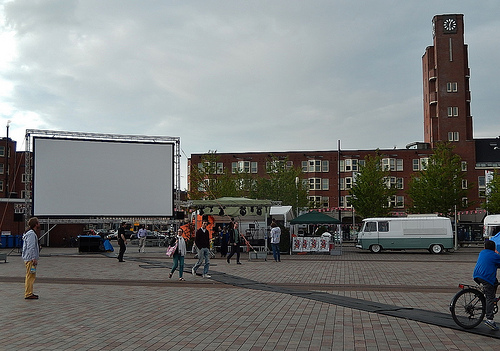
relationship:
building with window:
[185, 12, 500, 246] [446, 107, 453, 118]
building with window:
[185, 12, 500, 246] [313, 160, 322, 172]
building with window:
[185, 12, 500, 246] [247, 161, 258, 176]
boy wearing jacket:
[469, 238, 499, 330] [472, 249, 500, 286]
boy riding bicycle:
[469, 238, 499, 330] [448, 283, 499, 335]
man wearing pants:
[21, 216, 47, 303] [21, 259, 40, 297]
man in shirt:
[21, 216, 47, 303] [21, 231, 40, 263]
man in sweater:
[191, 218, 215, 278] [194, 230, 213, 250]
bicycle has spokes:
[448, 283, 499, 335] [451, 290, 487, 330]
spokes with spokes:
[451, 290, 487, 330] [456, 293, 483, 319]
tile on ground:
[257, 309, 281, 330] [8, 246, 497, 342]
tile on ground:
[212, 318, 228, 331] [8, 246, 497, 342]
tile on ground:
[132, 321, 149, 332] [8, 246, 497, 342]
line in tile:
[286, 310, 299, 324] [286, 311, 307, 330]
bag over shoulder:
[164, 237, 179, 263] [176, 237, 179, 244]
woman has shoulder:
[166, 227, 189, 283] [176, 237, 179, 244]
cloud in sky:
[0, 9, 43, 115] [0, 4, 498, 192]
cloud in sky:
[1, 100, 74, 138] [0, 4, 498, 192]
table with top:
[75, 238, 101, 252] [75, 235, 100, 239]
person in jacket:
[468, 237, 499, 332] [473, 250, 499, 286]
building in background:
[185, 12, 500, 246] [0, 0, 499, 153]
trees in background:
[188, 132, 498, 207] [0, 0, 499, 153]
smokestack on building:
[5, 119, 11, 197] [2, 135, 31, 263]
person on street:
[190, 214, 218, 281] [1, 237, 499, 347]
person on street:
[165, 225, 189, 285] [1, 237, 499, 347]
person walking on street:
[190, 214, 218, 281] [1, 237, 499, 347]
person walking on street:
[165, 225, 189, 285] [1, 237, 499, 347]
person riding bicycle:
[468, 237, 499, 332] [448, 283, 499, 335]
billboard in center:
[22, 132, 185, 227] [9, 182, 499, 270]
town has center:
[5, 10, 498, 345] [9, 182, 499, 270]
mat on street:
[299, 280, 409, 322] [1, 237, 499, 347]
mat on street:
[207, 260, 256, 296] [1, 237, 499, 347]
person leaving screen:
[468, 237, 499, 332] [32, 141, 179, 216]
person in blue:
[468, 237, 499, 332] [470, 248, 499, 288]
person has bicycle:
[468, 237, 499, 332] [448, 283, 499, 335]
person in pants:
[21, 216, 47, 303] [21, 259, 40, 297]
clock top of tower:
[440, 18, 459, 36] [433, 10, 469, 144]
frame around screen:
[22, 134, 183, 227] [32, 141, 179, 216]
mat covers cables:
[299, 280, 409, 322] [286, 283, 414, 310]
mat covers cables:
[207, 260, 256, 296] [204, 268, 259, 289]